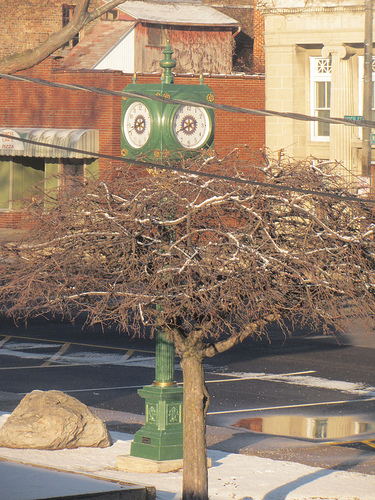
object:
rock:
[0, 388, 112, 452]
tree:
[0, 148, 375, 498]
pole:
[130, 165, 188, 461]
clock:
[121, 93, 159, 154]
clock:
[160, 87, 215, 153]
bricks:
[228, 130, 262, 144]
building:
[0, 1, 266, 260]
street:
[0, 269, 375, 476]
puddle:
[230, 402, 373, 443]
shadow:
[238, 452, 368, 500]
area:
[0, 316, 374, 498]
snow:
[182, 180, 243, 200]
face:
[178, 103, 210, 147]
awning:
[2, 123, 98, 161]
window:
[0, 157, 85, 213]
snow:
[257, 463, 292, 484]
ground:
[1, 439, 363, 500]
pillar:
[328, 44, 360, 198]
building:
[264, 2, 374, 222]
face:
[123, 104, 148, 142]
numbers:
[128, 104, 146, 115]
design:
[161, 403, 181, 427]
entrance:
[10, 158, 47, 231]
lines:
[1, 333, 158, 371]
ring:
[151, 378, 181, 390]